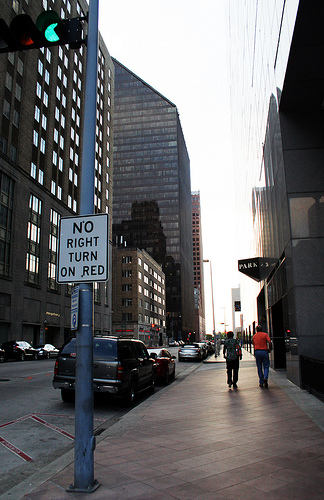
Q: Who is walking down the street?
A: Two men.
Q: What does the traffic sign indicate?
A: No right turn.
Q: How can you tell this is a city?
A: Tall buildings.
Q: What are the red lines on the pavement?
A: No parking.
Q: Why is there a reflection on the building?
A: Sunlight.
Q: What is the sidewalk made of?
A: Paving stones.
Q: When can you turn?
A: Not on red.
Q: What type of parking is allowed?
A: Parallel.